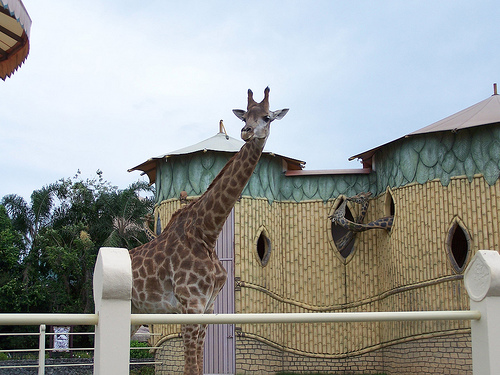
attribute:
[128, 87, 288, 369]
giraffe — large, wild, brown, tan, standing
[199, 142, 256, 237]
neck — thick, long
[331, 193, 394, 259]
giraffes — young, kissing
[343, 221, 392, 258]
necks — interlocking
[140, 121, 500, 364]
house — beautiful, yellow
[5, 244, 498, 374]
fence — metal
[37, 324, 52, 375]
rod — metallic, white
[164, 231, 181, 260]
spots — brown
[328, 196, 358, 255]
window — diamond shape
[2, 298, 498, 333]
railing — white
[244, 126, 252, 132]
holes — black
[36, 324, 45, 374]
post — wooden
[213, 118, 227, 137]
tip — pointy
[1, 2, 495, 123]
sky — clear, blue